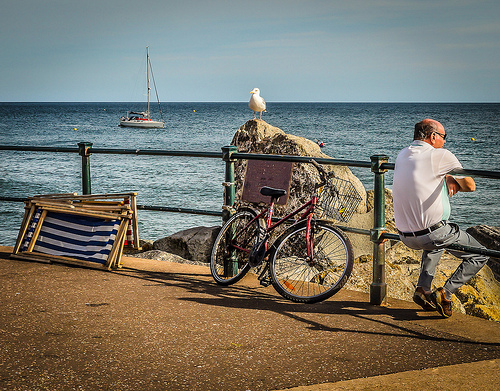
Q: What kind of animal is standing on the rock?
A: A bird.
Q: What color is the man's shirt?
A: White.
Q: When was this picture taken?
A: Daytime.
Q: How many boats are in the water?
A: One.